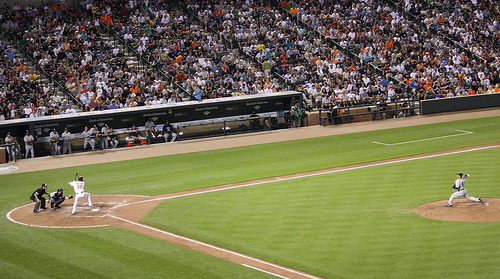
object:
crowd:
[3, 0, 499, 120]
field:
[4, 124, 499, 278]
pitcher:
[445, 169, 486, 211]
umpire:
[29, 180, 52, 215]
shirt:
[293, 109, 303, 121]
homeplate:
[84, 200, 104, 218]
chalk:
[124, 213, 311, 276]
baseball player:
[66, 168, 96, 218]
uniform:
[66, 180, 95, 212]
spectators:
[238, 82, 250, 93]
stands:
[182, 0, 421, 103]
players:
[160, 121, 179, 145]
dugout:
[6, 87, 313, 168]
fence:
[302, 89, 427, 125]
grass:
[295, 202, 402, 274]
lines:
[227, 256, 353, 279]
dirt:
[18, 137, 498, 274]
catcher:
[45, 184, 73, 212]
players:
[59, 129, 74, 156]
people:
[61, 106, 78, 115]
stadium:
[5, 2, 496, 277]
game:
[8, 104, 494, 277]